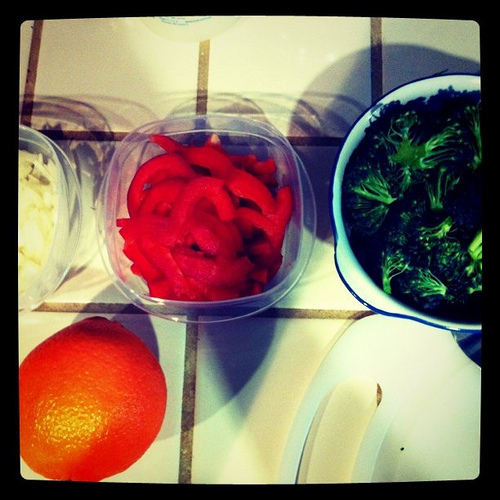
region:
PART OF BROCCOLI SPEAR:
[385, 112, 427, 162]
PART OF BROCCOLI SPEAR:
[361, 174, 393, 211]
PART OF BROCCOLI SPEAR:
[408, 200, 451, 247]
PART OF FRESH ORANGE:
[28, 340, 84, 377]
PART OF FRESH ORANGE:
[115, 352, 151, 414]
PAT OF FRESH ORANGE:
[20, 411, 52, 461]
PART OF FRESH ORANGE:
[91, 435, 146, 472]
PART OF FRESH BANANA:
[345, 385, 370, 431]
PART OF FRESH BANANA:
[305, 424, 347, 463]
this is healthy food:
[47, 130, 495, 398]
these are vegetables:
[94, 124, 437, 406]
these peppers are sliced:
[129, 168, 269, 265]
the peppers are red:
[146, 155, 238, 241]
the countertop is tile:
[167, 329, 284, 491]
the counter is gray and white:
[165, 326, 234, 408]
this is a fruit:
[42, 341, 172, 451]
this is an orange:
[60, 335, 169, 470]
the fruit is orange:
[39, 333, 139, 443]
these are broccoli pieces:
[358, 154, 413, 238]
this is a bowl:
[85, 74, 345, 336]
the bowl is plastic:
[86, 81, 354, 353]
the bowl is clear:
[65, 61, 349, 365]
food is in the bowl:
[76, 62, 342, 368]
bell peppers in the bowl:
[92, 80, 317, 340]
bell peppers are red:
[105, 99, 299, 316]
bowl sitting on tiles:
[30, 39, 420, 491]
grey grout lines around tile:
[11, 38, 365, 493]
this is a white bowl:
[309, 32, 490, 347]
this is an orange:
[19, 277, 188, 487]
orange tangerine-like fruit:
[20, 318, 167, 480]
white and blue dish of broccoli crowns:
[333, 91, 484, 332]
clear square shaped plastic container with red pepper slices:
[94, 115, 318, 324]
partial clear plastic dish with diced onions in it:
[20, 120, 80, 313]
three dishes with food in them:
[16, 69, 480, 336]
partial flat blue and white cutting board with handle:
[276, 311, 481, 481]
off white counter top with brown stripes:
[21, 23, 481, 472]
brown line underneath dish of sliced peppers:
[175, 31, 210, 480]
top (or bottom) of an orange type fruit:
[85, 314, 125, 329]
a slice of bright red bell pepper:
[138, 235, 191, 298]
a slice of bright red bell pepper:
[122, 237, 158, 282]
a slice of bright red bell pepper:
[162, 179, 235, 250]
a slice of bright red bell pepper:
[174, 252, 219, 282]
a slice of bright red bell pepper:
[207, 253, 253, 286]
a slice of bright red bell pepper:
[232, 205, 278, 247]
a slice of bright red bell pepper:
[127, 156, 191, 212]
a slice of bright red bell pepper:
[235, 151, 279, 178]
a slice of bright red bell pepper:
[147, 131, 178, 153]